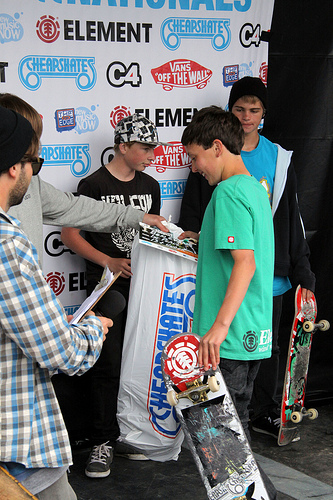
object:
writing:
[258, 329, 274, 348]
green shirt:
[191, 173, 276, 362]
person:
[181, 105, 274, 339]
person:
[221, 75, 320, 322]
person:
[76, 107, 163, 294]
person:
[0, 90, 170, 273]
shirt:
[238, 132, 291, 299]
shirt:
[8, 170, 147, 273]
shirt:
[0, 206, 107, 471]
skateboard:
[275, 283, 330, 447]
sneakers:
[83, 440, 115, 480]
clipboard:
[63, 267, 123, 326]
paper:
[64, 268, 117, 324]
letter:
[68, 271, 79, 294]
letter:
[96, 22, 116, 44]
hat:
[113, 111, 174, 150]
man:
[0, 109, 113, 499]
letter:
[151, 106, 165, 128]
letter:
[85, 20, 95, 44]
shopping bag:
[114, 213, 202, 467]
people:
[59, 113, 161, 478]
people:
[0, 93, 168, 276]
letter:
[115, 20, 126, 45]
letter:
[106, 60, 128, 90]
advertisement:
[149, 58, 214, 94]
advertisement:
[34, 14, 155, 47]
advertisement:
[159, 13, 232, 53]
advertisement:
[51, 101, 100, 137]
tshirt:
[76, 167, 164, 301]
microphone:
[92, 289, 127, 318]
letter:
[126, 21, 141, 45]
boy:
[175, 74, 314, 444]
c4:
[104, 59, 145, 89]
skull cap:
[228, 76, 268, 113]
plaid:
[0, 204, 103, 473]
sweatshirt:
[178, 139, 316, 299]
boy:
[177, 105, 277, 499]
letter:
[73, 18, 87, 43]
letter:
[140, 22, 155, 43]